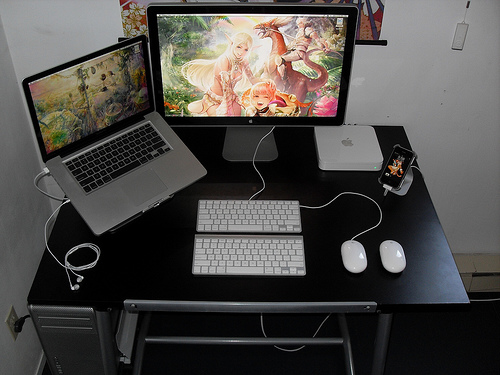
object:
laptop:
[23, 34, 207, 233]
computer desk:
[44, 271, 472, 310]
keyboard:
[196, 198, 305, 232]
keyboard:
[195, 237, 305, 273]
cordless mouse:
[381, 241, 404, 272]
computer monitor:
[146, 10, 352, 122]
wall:
[359, 52, 500, 114]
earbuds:
[44, 197, 101, 291]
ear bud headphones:
[60, 240, 106, 290]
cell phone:
[381, 142, 411, 187]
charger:
[375, 185, 401, 197]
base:
[221, 128, 284, 163]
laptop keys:
[83, 154, 128, 173]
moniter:
[40, 67, 141, 121]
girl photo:
[208, 34, 251, 113]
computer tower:
[34, 306, 106, 370]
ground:
[31, 318, 500, 366]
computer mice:
[340, 239, 369, 274]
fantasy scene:
[181, 34, 337, 114]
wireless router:
[316, 127, 385, 168]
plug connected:
[14, 318, 30, 331]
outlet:
[7, 307, 26, 339]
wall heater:
[449, 254, 499, 292]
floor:
[398, 313, 498, 371]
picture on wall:
[355, 4, 386, 44]